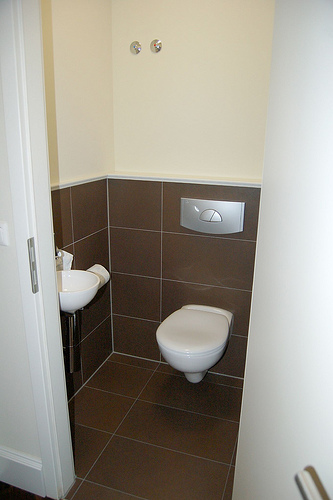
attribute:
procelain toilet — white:
[147, 293, 231, 388]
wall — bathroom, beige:
[45, 0, 279, 191]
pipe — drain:
[61, 314, 83, 377]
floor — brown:
[56, 348, 242, 499]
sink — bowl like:
[61, 257, 107, 317]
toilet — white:
[151, 310, 233, 393]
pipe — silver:
[67, 315, 79, 373]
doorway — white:
[4, 22, 88, 487]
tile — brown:
[107, 182, 163, 244]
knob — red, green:
[149, 40, 162, 51]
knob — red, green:
[128, 40, 143, 54]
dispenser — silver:
[173, 192, 249, 240]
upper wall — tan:
[37, 0, 277, 186]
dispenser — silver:
[178, 195, 245, 237]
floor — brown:
[101, 393, 228, 470]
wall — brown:
[53, 174, 259, 385]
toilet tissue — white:
[89, 250, 112, 281]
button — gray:
[196, 206, 223, 226]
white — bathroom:
[270, 93, 323, 349]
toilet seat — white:
[156, 307, 225, 358]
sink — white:
[53, 262, 94, 303]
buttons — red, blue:
[120, 29, 170, 58]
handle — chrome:
[27, 243, 45, 290]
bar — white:
[296, 465, 327, 499]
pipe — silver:
[66, 310, 75, 374]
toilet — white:
[158, 301, 236, 383]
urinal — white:
[55, 250, 110, 313]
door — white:
[226, 0, 326, 495]